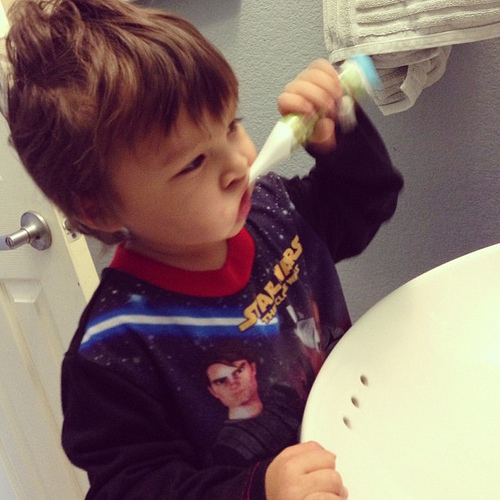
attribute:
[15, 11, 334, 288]
boy — serious, brushing, looking, little, white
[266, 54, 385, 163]
brush — eletric, white, electric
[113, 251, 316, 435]
shirt — blue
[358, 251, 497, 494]
sink — white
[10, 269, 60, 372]
door — white, open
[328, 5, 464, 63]
towel — hanging, hung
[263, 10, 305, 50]
wall — grey, blue